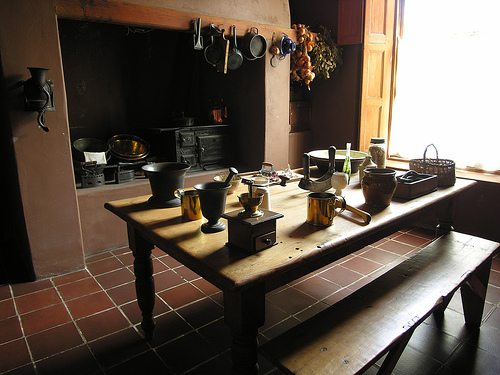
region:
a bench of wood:
[250, 215, 499, 374]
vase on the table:
[358, 161, 401, 216]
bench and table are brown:
[97, 128, 493, 370]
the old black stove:
[159, 118, 234, 171]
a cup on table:
[302, 184, 347, 233]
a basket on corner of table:
[407, 141, 460, 186]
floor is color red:
[3, 231, 499, 373]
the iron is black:
[73, 156, 110, 192]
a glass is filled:
[365, 133, 390, 170]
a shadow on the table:
[283, 216, 317, 249]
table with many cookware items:
[133, 138, 466, 295]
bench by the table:
[250, 235, 492, 359]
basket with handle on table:
[398, 140, 458, 185]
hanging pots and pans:
[177, 20, 269, 76]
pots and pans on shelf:
[78, 129, 152, 166]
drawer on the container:
[243, 223, 286, 254]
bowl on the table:
[305, 138, 370, 173]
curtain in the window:
[391, 55, 497, 161]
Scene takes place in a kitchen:
[10, 11, 485, 368]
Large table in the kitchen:
[114, 126, 468, 368]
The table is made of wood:
[112, 145, 469, 352]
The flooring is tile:
[9, 222, 466, 369]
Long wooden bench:
[256, 226, 496, 373]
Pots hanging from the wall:
[183, 14, 285, 76]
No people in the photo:
[12, 9, 494, 366]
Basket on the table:
[407, 142, 460, 187]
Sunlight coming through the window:
[384, 3, 493, 175]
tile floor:
[52, 295, 130, 337]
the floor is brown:
[56, 294, 116, 345]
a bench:
[328, 296, 387, 365]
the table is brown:
[232, 268, 256, 278]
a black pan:
[245, 33, 267, 55]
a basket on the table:
[433, 164, 456, 182]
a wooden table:
[281, 229, 310, 252]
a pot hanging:
[248, 32, 269, 58]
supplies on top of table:
[131, 118, 426, 253]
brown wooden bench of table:
[284, 229, 489, 373]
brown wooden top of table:
[208, 258, 269, 290]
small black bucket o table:
[147, 151, 188, 203]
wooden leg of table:
[128, 236, 160, 341]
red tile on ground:
[74, 289, 108, 324]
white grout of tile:
[75, 321, 92, 348]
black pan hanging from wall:
[241, 22, 272, 56]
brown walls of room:
[28, 131, 72, 276]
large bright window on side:
[400, 19, 497, 173]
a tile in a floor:
[394, 227, 423, 250]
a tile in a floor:
[363, 243, 397, 263]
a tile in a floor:
[347, 252, 381, 272]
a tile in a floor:
[326, 264, 362, 281]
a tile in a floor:
[295, 276, 337, 301]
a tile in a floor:
[272, 285, 312, 314]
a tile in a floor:
[253, 302, 282, 332]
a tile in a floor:
[181, 295, 221, 328]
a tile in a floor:
[153, 281, 205, 307]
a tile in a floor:
[16, 285, 59, 313]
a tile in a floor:
[20, 305, 73, 333]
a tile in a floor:
[58, 287, 107, 317]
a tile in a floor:
[22, 324, 81, 354]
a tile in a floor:
[70, 298, 129, 339]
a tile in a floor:
[85, 330, 147, 362]